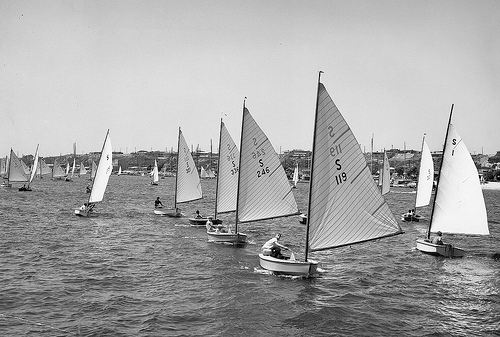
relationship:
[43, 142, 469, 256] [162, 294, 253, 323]
sailboats in ocean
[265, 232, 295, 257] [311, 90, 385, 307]
man steering boat 119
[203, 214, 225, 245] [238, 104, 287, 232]
man in boat 246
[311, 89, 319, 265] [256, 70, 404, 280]
mast on boat 119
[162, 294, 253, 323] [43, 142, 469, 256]
ocean under sailboats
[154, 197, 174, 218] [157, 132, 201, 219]
person on boat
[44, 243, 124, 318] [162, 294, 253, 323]
waves on ocean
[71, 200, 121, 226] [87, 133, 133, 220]
person sitting on sailboat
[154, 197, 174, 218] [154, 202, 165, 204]
person in dark top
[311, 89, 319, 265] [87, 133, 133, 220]
mast of sailboat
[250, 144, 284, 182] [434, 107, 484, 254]
writing on sail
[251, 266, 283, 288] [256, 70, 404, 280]
splashes around boat 119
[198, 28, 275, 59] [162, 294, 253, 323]
sky over ocean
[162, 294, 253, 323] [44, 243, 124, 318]
ocean with waves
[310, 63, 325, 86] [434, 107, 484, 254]
tip of sail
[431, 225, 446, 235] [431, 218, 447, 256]
hat on guy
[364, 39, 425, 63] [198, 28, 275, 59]
clouds in sky